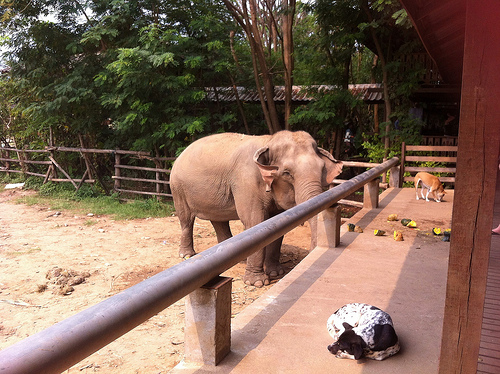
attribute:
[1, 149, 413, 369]
railing — metal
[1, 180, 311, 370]
dirt — large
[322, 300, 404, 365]
dog — small, black, white, pictured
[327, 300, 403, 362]
dog — pictured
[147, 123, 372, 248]
elephant — gray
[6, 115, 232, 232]
fence — wood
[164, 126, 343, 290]
elephant — pictured, standing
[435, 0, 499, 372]
pillar — large, wooden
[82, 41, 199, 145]
leaves — green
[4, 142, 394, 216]
fence — wooden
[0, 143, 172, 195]
fence — wood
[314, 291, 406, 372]
dog — black, white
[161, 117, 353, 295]
elephant — pictured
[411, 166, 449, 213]
dog — small, brown, white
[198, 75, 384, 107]
roof — slanted, metal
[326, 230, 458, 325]
porch — black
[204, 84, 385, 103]
roof — tin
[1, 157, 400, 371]
pole — large, metal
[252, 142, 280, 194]
ear — flapping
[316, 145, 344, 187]
ear — flapping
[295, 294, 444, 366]
dog — spotted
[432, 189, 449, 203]
head — down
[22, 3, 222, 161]
trees — large, leafy, green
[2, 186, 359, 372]
dirt — brown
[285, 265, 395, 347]
dog — sniffing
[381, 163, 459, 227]
dog — sniffing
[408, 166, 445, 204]
dog — tan, white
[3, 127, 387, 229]
fence — wooden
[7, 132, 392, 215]
fence — wood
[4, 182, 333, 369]
surface — dirt